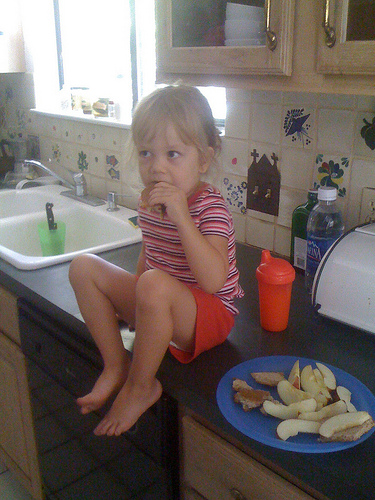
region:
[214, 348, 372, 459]
Blue plate with food.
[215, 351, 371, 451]
Apples on a plate.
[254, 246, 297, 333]
Orange cup on a counter.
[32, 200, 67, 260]
Knife in a green cup.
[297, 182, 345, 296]
Water bottle with a white cap.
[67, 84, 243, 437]
Child eating on a counter.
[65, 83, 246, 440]
Child wearing orange shorts.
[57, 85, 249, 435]
Child with a stripped shirt.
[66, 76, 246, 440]
Child eating a sandwich.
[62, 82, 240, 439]
Child not wearing socks.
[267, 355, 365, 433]
Apple slices on blue plate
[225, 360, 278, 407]
Toasted bread on blue plate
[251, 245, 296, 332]
Orange sippy cup filled with liquid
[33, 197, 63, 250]
Knife in green cup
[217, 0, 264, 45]
Bowls in cabinet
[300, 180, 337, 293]
Plastic bottle of water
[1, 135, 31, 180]
Blender on counter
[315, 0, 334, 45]
Cabinet door handle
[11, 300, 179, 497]
Black dishwasher in cabinet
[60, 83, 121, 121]
Decorations in kitchen window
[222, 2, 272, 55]
stack of white bowls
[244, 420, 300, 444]
apple slice on blue plate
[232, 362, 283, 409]
pieces of bread on blue plate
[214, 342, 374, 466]
blue plate on dark counter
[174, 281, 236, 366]
child wearing orange shorts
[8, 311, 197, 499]
black dishwasher set among cabinets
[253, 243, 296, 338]
bright orange children's cup on counter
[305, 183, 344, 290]
bottle of water on counter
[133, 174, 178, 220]
child holding food up to mouth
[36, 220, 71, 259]
green cup in white sink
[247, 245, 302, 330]
red drinking cup with spout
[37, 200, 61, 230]
large black knife with handle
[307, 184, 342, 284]
large bottled water with white lid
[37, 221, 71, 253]
large clear blue cup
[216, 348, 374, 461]
round blue dinner plate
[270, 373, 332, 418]
wedges of peeled apples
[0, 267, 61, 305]
portion of black counter top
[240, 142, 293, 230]
lighting fixture encased in brown cover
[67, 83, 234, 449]
young child eating a sandwich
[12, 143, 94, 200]
silver faucet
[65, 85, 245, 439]
Little girl sitting on counter.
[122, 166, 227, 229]
Girl eating a sandwich.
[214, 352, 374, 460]
Bread and sliced apples on plate.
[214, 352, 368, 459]
Blue plate sitting on counter.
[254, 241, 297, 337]
Orange water cup sitting on counter.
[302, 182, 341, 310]
Water bottle sitting on counter.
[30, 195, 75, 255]
Cup with knife sitting in sink.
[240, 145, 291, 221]
Light switch on wall.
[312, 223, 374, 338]
Bread box on counter.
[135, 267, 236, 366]
Girl wearing orange shorts.